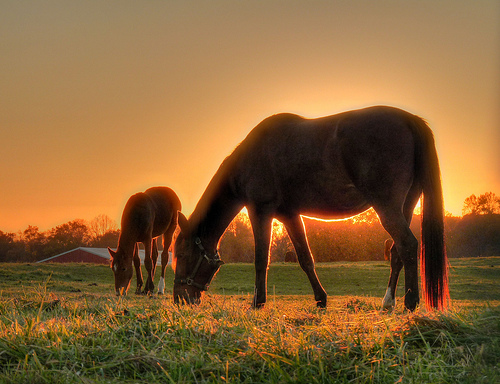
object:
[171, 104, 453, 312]
horses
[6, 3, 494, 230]
sky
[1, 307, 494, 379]
grass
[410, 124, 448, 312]
tail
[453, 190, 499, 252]
trees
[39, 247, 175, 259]
roof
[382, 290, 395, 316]
foot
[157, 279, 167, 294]
foot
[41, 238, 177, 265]
building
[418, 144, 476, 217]
sunset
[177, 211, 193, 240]
ears